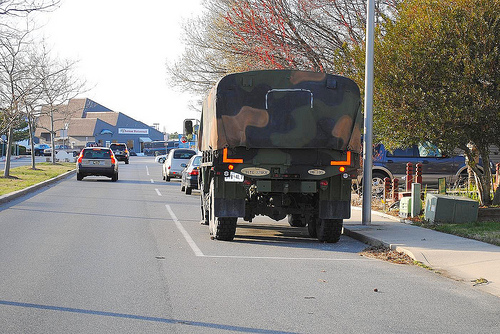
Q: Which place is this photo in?
A: It is at the street.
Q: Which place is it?
A: It is a street.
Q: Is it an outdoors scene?
A: Yes, it is outdoors.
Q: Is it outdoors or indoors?
A: It is outdoors.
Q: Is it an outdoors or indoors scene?
A: It is outdoors.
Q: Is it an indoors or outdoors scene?
A: It is outdoors.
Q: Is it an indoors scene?
A: No, it is outdoors.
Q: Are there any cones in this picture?
A: No, there are no cones.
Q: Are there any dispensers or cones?
A: No, there are no cones or dispensers.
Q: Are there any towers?
A: No, there are no towers.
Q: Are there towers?
A: No, there are no towers.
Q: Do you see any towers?
A: No, there are no towers.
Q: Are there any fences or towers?
A: No, there are no towers or fences.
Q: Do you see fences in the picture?
A: No, there are no fences.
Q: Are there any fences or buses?
A: No, there are no fences or buses.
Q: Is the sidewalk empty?
A: Yes, the sidewalk is empty.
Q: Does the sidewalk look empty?
A: Yes, the sidewalk is empty.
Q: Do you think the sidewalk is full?
A: No, the sidewalk is empty.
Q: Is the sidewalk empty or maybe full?
A: The sidewalk is empty.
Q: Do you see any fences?
A: No, there are no fences.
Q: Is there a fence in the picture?
A: No, there are no fences.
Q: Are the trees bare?
A: Yes, the trees are bare.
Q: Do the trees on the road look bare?
A: Yes, the trees are bare.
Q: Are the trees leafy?
A: No, the trees are bare.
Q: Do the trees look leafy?
A: No, the trees are bare.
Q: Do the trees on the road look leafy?
A: No, the trees are bare.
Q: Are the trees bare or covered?
A: The trees are bare.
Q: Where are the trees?
A: The trees are on the road.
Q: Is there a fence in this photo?
A: No, there are no fences.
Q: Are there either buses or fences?
A: No, there are no fences or buses.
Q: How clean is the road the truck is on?
A: The road is clean.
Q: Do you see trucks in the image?
A: Yes, there is a truck.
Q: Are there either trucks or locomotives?
A: Yes, there is a truck.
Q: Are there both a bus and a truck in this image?
A: No, there is a truck but no buses.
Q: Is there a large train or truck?
A: Yes, there is a large truck.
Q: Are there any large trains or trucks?
A: Yes, there is a large truck.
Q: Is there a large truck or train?
A: Yes, there is a large truck.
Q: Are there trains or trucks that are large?
A: Yes, the truck is large.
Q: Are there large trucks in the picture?
A: Yes, there is a large truck.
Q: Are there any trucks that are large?
A: Yes, there is a large truck.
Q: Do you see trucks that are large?
A: Yes, there is a truck that is large.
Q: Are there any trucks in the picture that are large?
A: Yes, there is a truck that is large.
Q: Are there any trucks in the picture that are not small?
A: Yes, there is a large truck.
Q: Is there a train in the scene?
A: No, there are no trains.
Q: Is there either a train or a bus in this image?
A: No, there are no trains or buses.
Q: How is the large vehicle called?
A: The vehicle is a truck.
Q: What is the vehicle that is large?
A: The vehicle is a truck.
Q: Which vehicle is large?
A: The vehicle is a truck.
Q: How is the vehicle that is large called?
A: The vehicle is a truck.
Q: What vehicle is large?
A: The vehicle is a truck.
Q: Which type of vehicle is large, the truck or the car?
A: The truck is large.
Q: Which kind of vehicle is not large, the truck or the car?
A: The car is not large.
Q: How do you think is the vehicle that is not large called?
A: The vehicle is a car.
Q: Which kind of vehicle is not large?
A: The vehicle is a car.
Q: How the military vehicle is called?
A: The vehicle is a truck.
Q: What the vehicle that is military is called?
A: The vehicle is a truck.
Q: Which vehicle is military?
A: The vehicle is a truck.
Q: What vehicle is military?
A: The vehicle is a truck.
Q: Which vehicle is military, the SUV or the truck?
A: The truck is military.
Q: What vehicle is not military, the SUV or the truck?
A: The SUV is not military.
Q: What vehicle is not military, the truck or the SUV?
A: The SUV is not military.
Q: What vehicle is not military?
A: The vehicle is a SUV.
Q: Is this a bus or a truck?
A: This is a truck.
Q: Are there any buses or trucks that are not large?
A: No, there is a truck but it is large.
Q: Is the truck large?
A: Yes, the truck is large.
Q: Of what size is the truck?
A: The truck is large.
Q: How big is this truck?
A: The truck is large.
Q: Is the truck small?
A: No, the truck is large.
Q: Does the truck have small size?
A: No, the truck is large.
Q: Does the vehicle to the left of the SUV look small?
A: No, the truck is large.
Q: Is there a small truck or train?
A: No, there is a truck but it is large.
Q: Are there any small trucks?
A: No, there is a truck but it is large.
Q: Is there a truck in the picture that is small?
A: No, there is a truck but it is large.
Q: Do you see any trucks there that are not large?
A: No, there is a truck but it is large.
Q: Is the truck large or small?
A: The truck is large.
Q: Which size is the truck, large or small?
A: The truck is large.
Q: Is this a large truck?
A: Yes, this is a large truck.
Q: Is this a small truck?
A: No, this is a large truck.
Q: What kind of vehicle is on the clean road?
A: The vehicle is a truck.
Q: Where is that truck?
A: The truck is on the road.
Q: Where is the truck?
A: The truck is on the road.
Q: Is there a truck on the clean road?
A: Yes, there is a truck on the road.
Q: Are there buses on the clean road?
A: No, there is a truck on the road.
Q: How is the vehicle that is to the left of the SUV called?
A: The vehicle is a truck.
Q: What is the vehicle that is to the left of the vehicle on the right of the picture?
A: The vehicle is a truck.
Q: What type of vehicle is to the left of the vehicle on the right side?
A: The vehicle is a truck.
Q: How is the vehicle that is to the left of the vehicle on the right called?
A: The vehicle is a truck.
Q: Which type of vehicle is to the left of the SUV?
A: The vehicle is a truck.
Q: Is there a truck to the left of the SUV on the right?
A: Yes, there is a truck to the left of the SUV.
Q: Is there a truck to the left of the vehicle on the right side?
A: Yes, there is a truck to the left of the SUV.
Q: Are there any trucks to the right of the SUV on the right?
A: No, the truck is to the left of the SUV.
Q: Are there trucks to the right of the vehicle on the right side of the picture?
A: No, the truck is to the left of the SUV.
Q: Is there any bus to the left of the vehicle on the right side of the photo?
A: No, there is a truck to the left of the SUV.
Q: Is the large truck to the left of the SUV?
A: Yes, the truck is to the left of the SUV.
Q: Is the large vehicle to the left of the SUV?
A: Yes, the truck is to the left of the SUV.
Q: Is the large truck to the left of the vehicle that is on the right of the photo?
A: Yes, the truck is to the left of the SUV.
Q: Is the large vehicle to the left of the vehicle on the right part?
A: Yes, the truck is to the left of the SUV.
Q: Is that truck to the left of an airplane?
A: No, the truck is to the left of the SUV.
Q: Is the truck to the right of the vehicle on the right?
A: No, the truck is to the left of the SUV.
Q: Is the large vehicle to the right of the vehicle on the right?
A: No, the truck is to the left of the SUV.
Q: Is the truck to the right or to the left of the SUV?
A: The truck is to the left of the SUV.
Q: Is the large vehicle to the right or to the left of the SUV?
A: The truck is to the left of the SUV.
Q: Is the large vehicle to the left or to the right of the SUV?
A: The truck is to the left of the SUV.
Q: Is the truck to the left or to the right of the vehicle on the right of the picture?
A: The truck is to the left of the SUV.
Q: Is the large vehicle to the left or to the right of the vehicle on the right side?
A: The truck is to the left of the SUV.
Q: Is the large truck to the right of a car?
A: Yes, the truck is to the right of a car.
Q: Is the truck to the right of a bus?
A: No, the truck is to the right of a car.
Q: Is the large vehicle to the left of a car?
A: No, the truck is to the right of a car.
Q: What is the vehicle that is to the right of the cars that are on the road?
A: The vehicle is a truck.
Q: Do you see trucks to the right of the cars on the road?
A: Yes, there is a truck to the right of the cars.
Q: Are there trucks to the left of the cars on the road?
A: No, the truck is to the right of the cars.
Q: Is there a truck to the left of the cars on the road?
A: No, the truck is to the right of the cars.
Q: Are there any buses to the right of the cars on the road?
A: No, there is a truck to the right of the cars.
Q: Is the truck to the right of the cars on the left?
A: Yes, the truck is to the right of the cars.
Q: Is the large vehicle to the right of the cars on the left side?
A: Yes, the truck is to the right of the cars.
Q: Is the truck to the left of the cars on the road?
A: No, the truck is to the right of the cars.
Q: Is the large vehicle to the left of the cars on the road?
A: No, the truck is to the right of the cars.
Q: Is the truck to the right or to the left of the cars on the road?
A: The truck is to the right of the cars.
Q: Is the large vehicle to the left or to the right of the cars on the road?
A: The truck is to the right of the cars.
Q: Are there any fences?
A: No, there are no fences.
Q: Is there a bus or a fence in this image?
A: No, there are no fences or buses.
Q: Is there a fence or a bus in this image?
A: No, there are no fences or buses.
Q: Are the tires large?
A: Yes, the tires are large.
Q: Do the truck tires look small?
A: No, the tires are large.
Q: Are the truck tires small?
A: No, the tires are large.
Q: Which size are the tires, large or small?
A: The tires are large.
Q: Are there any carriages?
A: No, there are no carriages.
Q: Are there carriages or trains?
A: No, there are no carriages or trains.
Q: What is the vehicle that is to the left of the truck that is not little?
A: The vehicle is a car.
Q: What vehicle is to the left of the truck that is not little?
A: The vehicle is a car.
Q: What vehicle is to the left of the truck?
A: The vehicle is a car.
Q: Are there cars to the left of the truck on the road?
A: Yes, there is a car to the left of the truck.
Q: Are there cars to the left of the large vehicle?
A: Yes, there is a car to the left of the truck.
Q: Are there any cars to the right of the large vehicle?
A: No, the car is to the left of the truck.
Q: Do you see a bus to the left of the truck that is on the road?
A: No, there is a car to the left of the truck.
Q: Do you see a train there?
A: No, there are no trains.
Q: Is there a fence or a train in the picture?
A: No, there are no trains or fences.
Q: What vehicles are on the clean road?
A: The vehicles are cars.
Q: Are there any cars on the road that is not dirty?
A: Yes, there are cars on the road.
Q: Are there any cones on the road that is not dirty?
A: No, there are cars on the road.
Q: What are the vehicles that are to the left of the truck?
A: The vehicles are cars.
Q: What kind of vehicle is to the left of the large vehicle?
A: The vehicles are cars.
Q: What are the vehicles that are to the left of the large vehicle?
A: The vehicles are cars.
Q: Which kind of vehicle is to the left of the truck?
A: The vehicles are cars.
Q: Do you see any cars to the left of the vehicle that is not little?
A: Yes, there are cars to the left of the truck.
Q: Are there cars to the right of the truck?
A: No, the cars are to the left of the truck.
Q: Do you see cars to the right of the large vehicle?
A: No, the cars are to the left of the truck.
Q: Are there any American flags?
A: No, there are no American flags.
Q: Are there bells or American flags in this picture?
A: No, there are no American flags or bells.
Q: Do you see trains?
A: No, there are no trains.